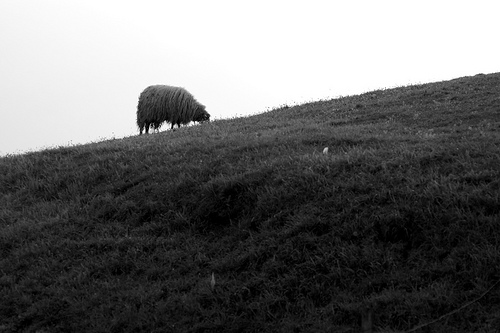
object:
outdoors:
[156, 6, 260, 70]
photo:
[0, 3, 497, 328]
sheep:
[133, 84, 209, 135]